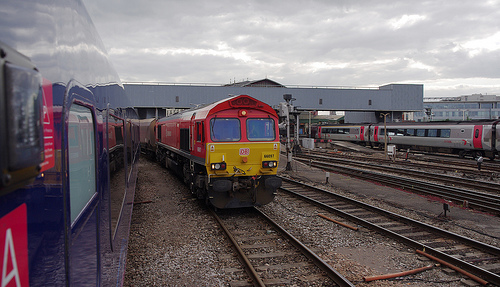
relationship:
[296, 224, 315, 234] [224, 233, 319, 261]
rocks on track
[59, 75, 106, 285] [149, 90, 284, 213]
door on side train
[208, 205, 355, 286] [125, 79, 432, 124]
track in station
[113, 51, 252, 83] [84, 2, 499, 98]
cloud in sky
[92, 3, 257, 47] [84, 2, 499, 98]
cloud in sky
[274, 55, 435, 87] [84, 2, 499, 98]
cloud in sky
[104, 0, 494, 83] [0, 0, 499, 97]
clouds in blue sky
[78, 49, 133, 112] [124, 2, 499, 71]
clouds in sky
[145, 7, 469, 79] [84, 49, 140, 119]
clouds in sky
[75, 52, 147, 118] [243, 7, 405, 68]
clouds in sky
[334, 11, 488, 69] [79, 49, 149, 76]
clouds in sky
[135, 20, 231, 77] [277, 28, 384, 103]
white clouds in blue sky